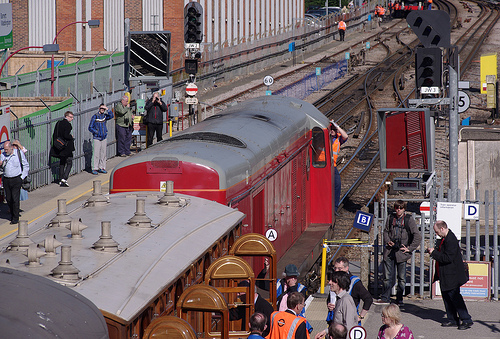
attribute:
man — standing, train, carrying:
[86, 91, 120, 183]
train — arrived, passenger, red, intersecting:
[72, 70, 354, 330]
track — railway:
[349, 51, 396, 108]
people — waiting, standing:
[11, 61, 200, 233]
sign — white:
[442, 85, 486, 118]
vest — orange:
[267, 306, 309, 335]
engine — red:
[133, 142, 216, 196]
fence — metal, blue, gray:
[71, 104, 105, 164]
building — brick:
[35, 3, 189, 75]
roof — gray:
[165, 91, 284, 192]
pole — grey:
[432, 91, 468, 207]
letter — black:
[441, 93, 472, 116]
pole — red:
[33, 56, 70, 120]